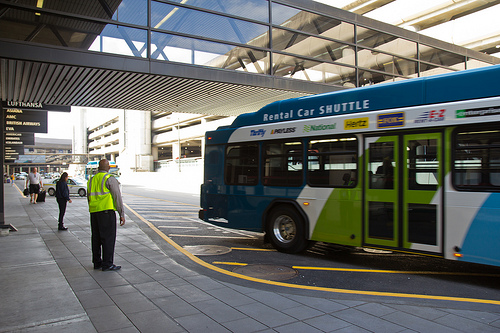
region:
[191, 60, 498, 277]
A blue bus on the road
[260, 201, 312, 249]
Rear right wheel of the bus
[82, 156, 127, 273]
Man standing on the street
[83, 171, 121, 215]
Green reflector vest worn by man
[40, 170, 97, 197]
Taxi car on the road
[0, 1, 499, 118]
Bridge way above the bus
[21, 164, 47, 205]
man walking while carrying his luggage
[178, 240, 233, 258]
Round sewer hole cover near the bus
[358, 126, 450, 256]
Door way of the bus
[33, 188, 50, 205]
Black luggage carried by man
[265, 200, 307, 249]
A black tire on a bus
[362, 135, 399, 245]
Door on a bus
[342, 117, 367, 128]
A company logo sticker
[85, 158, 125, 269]
A man standing outside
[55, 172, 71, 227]
A woman wearing a blue jacket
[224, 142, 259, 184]
A window on a big bus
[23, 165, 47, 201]
A man carrying luggage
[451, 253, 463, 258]
Side light on a bus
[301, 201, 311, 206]
A small light on a bus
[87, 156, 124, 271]
A man wearing a vest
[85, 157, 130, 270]
a man in a safety jacket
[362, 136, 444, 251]
a green bus door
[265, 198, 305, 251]
a large black rubber tire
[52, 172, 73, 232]
a person dressed in black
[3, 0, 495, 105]
an overhead glass walkway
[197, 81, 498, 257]
a large blue and white bus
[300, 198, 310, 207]
an orange light on the side of a bus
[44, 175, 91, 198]
a white car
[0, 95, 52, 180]
a bunch of black signs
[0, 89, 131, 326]
people waiting at a bus terminal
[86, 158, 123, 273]
man in a safety vest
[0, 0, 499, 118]
glass walkway above a road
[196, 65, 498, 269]
rental car shuttle bus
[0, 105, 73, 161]
signs for different airlines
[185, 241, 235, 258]
a man hole cover in the street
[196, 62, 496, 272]
blue and green rental car shuttle bus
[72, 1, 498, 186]
parking garage at the airport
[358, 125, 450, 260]
green and white door on a bus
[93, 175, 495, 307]
road in front of the airport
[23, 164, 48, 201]
person carrying their luggage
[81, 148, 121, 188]
the head of a man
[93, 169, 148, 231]
the arm of a man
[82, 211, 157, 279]
the legs of a man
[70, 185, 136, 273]
a man wearing pants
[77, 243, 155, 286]
a man wearing shoes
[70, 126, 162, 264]
the body of a man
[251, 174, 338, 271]
the wheel of a bus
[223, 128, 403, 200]
the side windows on a bus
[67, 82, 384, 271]
a man near a bus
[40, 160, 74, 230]
a woman near a bus